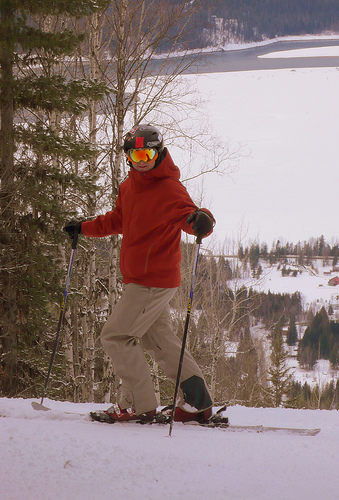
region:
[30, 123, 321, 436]
person is cross country skiing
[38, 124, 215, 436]
skier is holding a ski pole in each hand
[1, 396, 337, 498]
ground is covered in snow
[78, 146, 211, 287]
red snow jacket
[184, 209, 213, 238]
black gloves on a person's hand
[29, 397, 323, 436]
ski boots are attached to skis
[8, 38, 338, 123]
open river in snow covered landscape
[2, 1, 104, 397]
tall evergreen tree on a hill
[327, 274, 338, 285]
red house in a valley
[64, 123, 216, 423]
skier is wearing a protective helmet and goggles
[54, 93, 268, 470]
The person is up in the mountains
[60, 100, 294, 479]
The person is doing some snow skiing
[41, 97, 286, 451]
The person is close to a ski lodge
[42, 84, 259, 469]
The person is using snow skis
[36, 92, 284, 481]
The person is wearing ski boots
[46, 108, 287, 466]
A person is wearing a helmet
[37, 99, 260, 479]
A person is wearing warm clothing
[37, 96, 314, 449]
A person is on their vacation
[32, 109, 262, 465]
A person is holding ski poles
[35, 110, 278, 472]
A person is enjoying the day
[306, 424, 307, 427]
part of a snow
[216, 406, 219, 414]
part of a bench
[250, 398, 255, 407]
part of a tree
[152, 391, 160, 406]
part of a short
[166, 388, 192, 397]
edge of a pole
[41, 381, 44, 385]
part of a rail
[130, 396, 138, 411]
part of a skate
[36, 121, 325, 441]
skier stopped on the mountain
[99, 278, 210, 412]
light brown pants skier is wearing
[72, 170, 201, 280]
red orange jacket worn by skier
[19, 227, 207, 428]
black, blue, and yellow ski poles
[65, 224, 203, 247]
black handles of the ski poles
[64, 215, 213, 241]
black gloves skier is wearing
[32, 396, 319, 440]
white skis in the snow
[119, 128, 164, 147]
black helmet skier is wearing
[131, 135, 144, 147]
red sticker on black helmet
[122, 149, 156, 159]
reflective snow goggles man is wearing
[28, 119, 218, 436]
skier holds ski poles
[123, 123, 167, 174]
orange ski goggles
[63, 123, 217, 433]
skier wears a red sweatshirt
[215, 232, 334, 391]
trees growing on a snowy hill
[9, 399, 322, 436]
a pair of skis in the snow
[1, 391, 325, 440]
red ski boots on skis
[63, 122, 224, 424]
skier wears black gloves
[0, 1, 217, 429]
tall pine tree next to a skier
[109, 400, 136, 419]
silver straps on a ski boot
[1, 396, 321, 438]
snow covering some skis